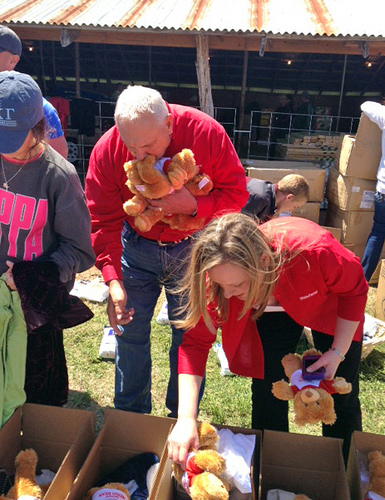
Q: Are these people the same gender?
A: No, they are both male and female.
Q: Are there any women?
A: Yes, there is a woman.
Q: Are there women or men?
A: Yes, there is a woman.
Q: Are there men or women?
A: Yes, there is a woman.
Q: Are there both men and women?
A: Yes, there are both a woman and a man.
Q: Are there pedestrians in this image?
A: No, there are no pedestrians.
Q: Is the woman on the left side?
A: Yes, the woman is on the left of the image.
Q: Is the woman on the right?
A: No, the woman is on the left of the image.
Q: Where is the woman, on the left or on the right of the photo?
A: The woman is on the left of the image.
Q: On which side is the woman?
A: The woman is on the left of the image.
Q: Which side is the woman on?
A: The woman is on the left of the image.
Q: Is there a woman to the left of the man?
A: Yes, there is a woman to the left of the man.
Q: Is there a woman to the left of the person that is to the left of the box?
A: Yes, there is a woman to the left of the man.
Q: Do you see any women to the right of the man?
A: No, the woman is to the left of the man.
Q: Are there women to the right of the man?
A: No, the woman is to the left of the man.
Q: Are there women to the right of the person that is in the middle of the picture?
A: No, the woman is to the left of the man.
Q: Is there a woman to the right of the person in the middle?
A: No, the woman is to the left of the man.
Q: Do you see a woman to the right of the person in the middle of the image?
A: No, the woman is to the left of the man.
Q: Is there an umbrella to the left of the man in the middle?
A: No, there is a woman to the left of the man.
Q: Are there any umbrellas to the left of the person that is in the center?
A: No, there is a woman to the left of the man.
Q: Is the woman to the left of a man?
A: Yes, the woman is to the left of a man.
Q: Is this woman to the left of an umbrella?
A: No, the woman is to the left of a man.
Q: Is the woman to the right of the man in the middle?
A: No, the woman is to the left of the man.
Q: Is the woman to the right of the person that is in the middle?
A: No, the woman is to the left of the man.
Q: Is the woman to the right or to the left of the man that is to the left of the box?
A: The woman is to the left of the man.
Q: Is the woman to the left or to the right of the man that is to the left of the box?
A: The woman is to the left of the man.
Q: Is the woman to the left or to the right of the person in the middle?
A: The woman is to the left of the man.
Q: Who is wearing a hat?
A: The woman is wearing a hat.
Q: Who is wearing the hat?
A: The woman is wearing a hat.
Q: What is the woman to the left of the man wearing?
A: The woman is wearing a hat.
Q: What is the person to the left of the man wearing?
A: The woman is wearing a hat.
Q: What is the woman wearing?
A: The woman is wearing a hat.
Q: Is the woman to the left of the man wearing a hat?
A: Yes, the woman is wearing a hat.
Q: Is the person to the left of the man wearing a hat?
A: Yes, the woman is wearing a hat.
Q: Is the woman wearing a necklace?
A: No, the woman is wearing a hat.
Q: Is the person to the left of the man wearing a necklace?
A: No, the woman is wearing a hat.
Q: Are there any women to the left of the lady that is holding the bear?
A: Yes, there is a woman to the left of the lady.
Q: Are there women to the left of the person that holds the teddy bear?
A: Yes, there is a woman to the left of the lady.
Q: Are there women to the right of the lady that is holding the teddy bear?
A: No, the woman is to the left of the lady.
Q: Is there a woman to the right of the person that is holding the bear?
A: No, the woman is to the left of the lady.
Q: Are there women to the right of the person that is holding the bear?
A: No, the woman is to the left of the lady.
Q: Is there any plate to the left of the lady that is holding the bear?
A: No, there is a woman to the left of the lady.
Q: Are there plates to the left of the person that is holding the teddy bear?
A: No, there is a woman to the left of the lady.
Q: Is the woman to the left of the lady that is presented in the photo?
A: Yes, the woman is to the left of the lady.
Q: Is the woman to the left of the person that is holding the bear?
A: Yes, the woman is to the left of the lady.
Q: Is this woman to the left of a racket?
A: No, the woman is to the left of the lady.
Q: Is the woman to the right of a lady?
A: No, the woman is to the left of a lady.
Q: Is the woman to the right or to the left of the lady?
A: The woman is to the left of the lady.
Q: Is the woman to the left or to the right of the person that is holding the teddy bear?
A: The woman is to the left of the lady.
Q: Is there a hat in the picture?
A: Yes, there is a hat.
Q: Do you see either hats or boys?
A: Yes, there is a hat.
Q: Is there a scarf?
A: No, there are no scarves.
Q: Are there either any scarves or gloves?
A: No, there are no scarves or gloves.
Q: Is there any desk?
A: No, there are no desks.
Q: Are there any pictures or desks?
A: No, there are no desks or pictures.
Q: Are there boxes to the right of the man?
A: Yes, there is a box to the right of the man.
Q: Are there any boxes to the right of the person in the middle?
A: Yes, there is a box to the right of the man.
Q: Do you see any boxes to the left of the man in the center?
A: No, the box is to the right of the man.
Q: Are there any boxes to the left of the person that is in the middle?
A: No, the box is to the right of the man.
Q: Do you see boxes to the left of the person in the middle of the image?
A: No, the box is to the right of the man.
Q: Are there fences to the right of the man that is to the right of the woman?
A: No, there is a box to the right of the man.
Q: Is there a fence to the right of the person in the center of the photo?
A: No, there is a box to the right of the man.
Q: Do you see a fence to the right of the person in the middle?
A: No, there is a box to the right of the man.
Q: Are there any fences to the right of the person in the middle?
A: No, there is a box to the right of the man.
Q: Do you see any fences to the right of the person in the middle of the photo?
A: No, there is a box to the right of the man.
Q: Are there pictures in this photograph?
A: No, there are no pictures.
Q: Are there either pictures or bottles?
A: No, there are no pictures or bottles.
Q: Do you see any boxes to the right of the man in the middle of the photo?
A: Yes, there is a box to the right of the man.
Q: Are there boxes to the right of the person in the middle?
A: Yes, there is a box to the right of the man.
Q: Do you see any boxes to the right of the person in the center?
A: Yes, there is a box to the right of the man.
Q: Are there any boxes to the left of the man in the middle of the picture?
A: No, the box is to the right of the man.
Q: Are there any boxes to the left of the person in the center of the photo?
A: No, the box is to the right of the man.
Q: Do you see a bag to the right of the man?
A: No, there is a box to the right of the man.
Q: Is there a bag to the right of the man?
A: No, there is a box to the right of the man.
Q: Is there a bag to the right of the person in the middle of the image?
A: No, there is a box to the right of the man.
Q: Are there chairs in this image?
A: No, there are no chairs.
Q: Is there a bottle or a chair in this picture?
A: No, there are no chairs or bottles.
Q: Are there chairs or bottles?
A: No, there are no chairs or bottles.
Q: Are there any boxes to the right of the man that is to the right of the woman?
A: Yes, there is a box to the right of the man.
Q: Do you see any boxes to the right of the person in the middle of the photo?
A: Yes, there is a box to the right of the man.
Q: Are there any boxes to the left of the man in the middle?
A: No, the box is to the right of the man.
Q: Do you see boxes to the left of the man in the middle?
A: No, the box is to the right of the man.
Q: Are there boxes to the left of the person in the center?
A: No, the box is to the right of the man.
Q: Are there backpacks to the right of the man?
A: No, there is a box to the right of the man.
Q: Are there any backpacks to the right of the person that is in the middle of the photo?
A: No, there is a box to the right of the man.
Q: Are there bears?
A: Yes, there is a bear.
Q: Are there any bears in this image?
A: Yes, there is a bear.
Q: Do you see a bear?
A: Yes, there is a bear.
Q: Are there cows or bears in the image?
A: Yes, there is a bear.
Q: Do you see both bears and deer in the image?
A: No, there is a bear but no deer.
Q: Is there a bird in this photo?
A: No, there are no birds.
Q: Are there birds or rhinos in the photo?
A: No, there are no birds or rhinos.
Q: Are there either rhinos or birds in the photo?
A: No, there are no birds or rhinos.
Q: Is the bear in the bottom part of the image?
A: Yes, the bear is in the bottom of the image.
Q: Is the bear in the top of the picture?
A: No, the bear is in the bottom of the image.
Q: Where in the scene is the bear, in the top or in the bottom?
A: The bear is in the bottom of the image.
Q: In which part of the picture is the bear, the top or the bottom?
A: The bear is in the bottom of the image.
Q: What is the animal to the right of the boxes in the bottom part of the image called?
A: The animal is a bear.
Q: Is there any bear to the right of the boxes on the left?
A: Yes, there is a bear to the right of the boxes.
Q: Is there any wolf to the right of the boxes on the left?
A: No, there is a bear to the right of the boxes.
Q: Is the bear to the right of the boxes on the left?
A: Yes, the bear is to the right of the boxes.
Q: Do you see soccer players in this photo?
A: No, there are no soccer players.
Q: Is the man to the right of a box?
A: No, the man is to the left of a box.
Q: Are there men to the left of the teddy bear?
A: Yes, there is a man to the left of the teddy bear.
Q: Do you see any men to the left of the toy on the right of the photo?
A: Yes, there is a man to the left of the teddy bear.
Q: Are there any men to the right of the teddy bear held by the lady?
A: No, the man is to the left of the teddy bear.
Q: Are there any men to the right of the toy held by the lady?
A: No, the man is to the left of the teddy bear.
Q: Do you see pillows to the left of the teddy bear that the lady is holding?
A: No, there is a man to the left of the teddy bear.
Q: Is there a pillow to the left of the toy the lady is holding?
A: No, there is a man to the left of the teddy bear.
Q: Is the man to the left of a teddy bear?
A: Yes, the man is to the left of a teddy bear.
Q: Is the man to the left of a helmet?
A: No, the man is to the left of a teddy bear.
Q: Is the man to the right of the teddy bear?
A: No, the man is to the left of the teddy bear.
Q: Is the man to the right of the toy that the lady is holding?
A: No, the man is to the left of the teddy bear.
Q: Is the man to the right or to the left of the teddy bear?
A: The man is to the left of the teddy bear.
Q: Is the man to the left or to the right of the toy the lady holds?
A: The man is to the left of the teddy bear.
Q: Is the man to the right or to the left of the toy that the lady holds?
A: The man is to the left of the teddy bear.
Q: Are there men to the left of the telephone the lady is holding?
A: Yes, there is a man to the left of the telephone.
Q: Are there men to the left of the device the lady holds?
A: Yes, there is a man to the left of the telephone.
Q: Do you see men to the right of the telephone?
A: No, the man is to the left of the telephone.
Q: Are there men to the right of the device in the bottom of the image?
A: No, the man is to the left of the telephone.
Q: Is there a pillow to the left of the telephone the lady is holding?
A: No, there is a man to the left of the telephone.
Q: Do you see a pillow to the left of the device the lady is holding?
A: No, there is a man to the left of the telephone.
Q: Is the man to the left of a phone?
A: Yes, the man is to the left of a phone.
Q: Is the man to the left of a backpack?
A: No, the man is to the left of a phone.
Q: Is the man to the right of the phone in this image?
A: No, the man is to the left of the phone.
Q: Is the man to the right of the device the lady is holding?
A: No, the man is to the left of the phone.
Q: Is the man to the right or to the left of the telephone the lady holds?
A: The man is to the left of the telephone.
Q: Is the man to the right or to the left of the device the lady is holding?
A: The man is to the left of the telephone.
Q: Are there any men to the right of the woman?
A: Yes, there is a man to the right of the woman.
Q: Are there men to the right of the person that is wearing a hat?
A: Yes, there is a man to the right of the woman.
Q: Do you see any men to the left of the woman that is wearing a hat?
A: No, the man is to the right of the woman.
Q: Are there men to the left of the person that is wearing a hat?
A: No, the man is to the right of the woman.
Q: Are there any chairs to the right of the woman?
A: No, there is a man to the right of the woman.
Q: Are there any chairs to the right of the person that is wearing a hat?
A: No, there is a man to the right of the woman.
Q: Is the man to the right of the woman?
A: Yes, the man is to the right of the woman.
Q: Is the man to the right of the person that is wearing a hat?
A: Yes, the man is to the right of the woman.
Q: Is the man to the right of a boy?
A: No, the man is to the right of the woman.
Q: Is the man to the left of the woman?
A: No, the man is to the right of the woman.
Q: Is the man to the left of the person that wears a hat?
A: No, the man is to the right of the woman.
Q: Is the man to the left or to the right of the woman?
A: The man is to the right of the woman.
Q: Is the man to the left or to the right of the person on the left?
A: The man is to the right of the woman.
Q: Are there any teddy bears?
A: Yes, there is a teddy bear.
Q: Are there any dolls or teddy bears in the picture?
A: Yes, there is a teddy bear.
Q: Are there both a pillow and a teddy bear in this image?
A: No, there is a teddy bear but no pillows.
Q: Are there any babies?
A: No, there are no babies.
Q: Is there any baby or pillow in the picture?
A: No, there are no babies or pillows.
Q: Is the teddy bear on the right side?
A: Yes, the teddy bear is on the right of the image.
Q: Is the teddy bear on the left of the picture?
A: No, the teddy bear is on the right of the image.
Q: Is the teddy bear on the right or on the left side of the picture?
A: The teddy bear is on the right of the image.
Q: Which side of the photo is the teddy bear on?
A: The teddy bear is on the right of the image.